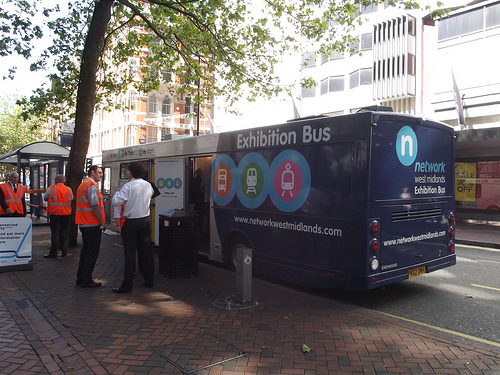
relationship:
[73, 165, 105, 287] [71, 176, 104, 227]
man wears vest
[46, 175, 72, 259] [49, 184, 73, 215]
man wears vest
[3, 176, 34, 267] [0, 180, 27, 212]
man wears vest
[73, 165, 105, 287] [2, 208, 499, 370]
man on sidewalk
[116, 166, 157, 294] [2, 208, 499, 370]
man on sidewalk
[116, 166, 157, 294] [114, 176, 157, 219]
man wears shirt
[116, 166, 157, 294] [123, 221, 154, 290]
man wears pants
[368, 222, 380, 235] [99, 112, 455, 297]
light on bus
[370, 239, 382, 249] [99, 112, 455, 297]
light on bus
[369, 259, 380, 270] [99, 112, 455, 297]
light on bus